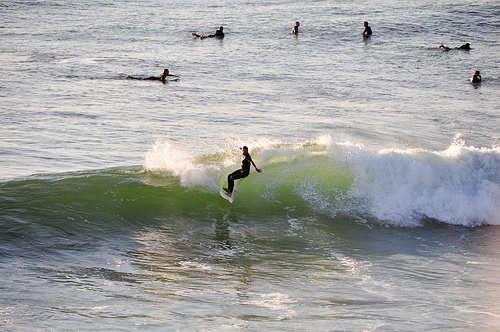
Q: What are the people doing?
A: Riding surfboards.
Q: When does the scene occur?
A: Daytime.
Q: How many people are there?
A: Seven.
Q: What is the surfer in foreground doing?
A: Riding a wave.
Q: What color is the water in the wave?
A: Greenish.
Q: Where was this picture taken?
A: In the ocean.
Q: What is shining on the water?
A: Sunlight.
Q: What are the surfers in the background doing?
A: Lying on their surfboards.